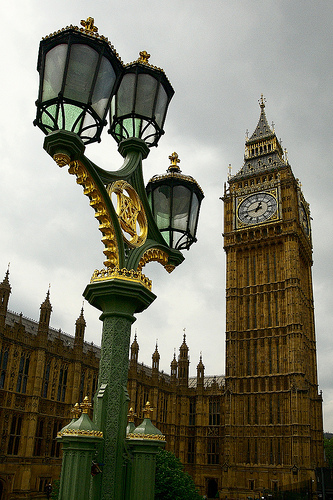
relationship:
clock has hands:
[234, 186, 283, 229] [241, 198, 264, 218]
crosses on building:
[242, 118, 287, 159] [217, 95, 323, 499]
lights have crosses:
[34, 16, 203, 257] [77, 15, 182, 169]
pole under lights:
[57, 278, 169, 500] [34, 16, 203, 257]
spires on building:
[1, 265, 208, 389] [0, 95, 322, 499]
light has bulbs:
[106, 47, 173, 150] [121, 109, 157, 140]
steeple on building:
[75, 294, 89, 346] [0, 95, 322, 499]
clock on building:
[234, 186, 283, 229] [0, 95, 322, 499]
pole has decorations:
[57, 278, 169, 500] [53, 146, 177, 293]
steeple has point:
[75, 294, 89, 346] [77, 303, 87, 320]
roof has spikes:
[3, 309, 228, 391] [10, 312, 36, 331]